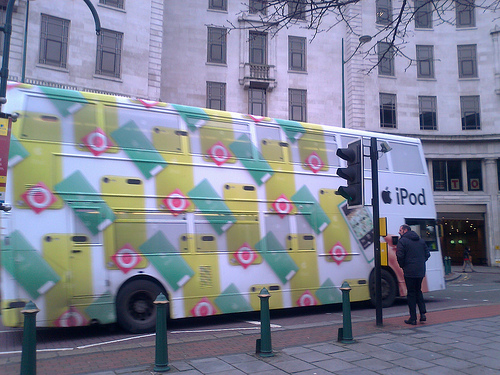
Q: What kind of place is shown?
A: It is a road.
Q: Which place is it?
A: It is a road.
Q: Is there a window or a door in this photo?
A: Yes, there is a window.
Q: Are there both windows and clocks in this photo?
A: No, there is a window but no clocks.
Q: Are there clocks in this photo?
A: No, there are no clocks.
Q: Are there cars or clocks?
A: No, there are no clocks or cars.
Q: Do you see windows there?
A: Yes, there is a window.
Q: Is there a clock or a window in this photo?
A: Yes, there is a window.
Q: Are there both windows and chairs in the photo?
A: No, there is a window but no chairs.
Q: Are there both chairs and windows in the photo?
A: No, there is a window but no chairs.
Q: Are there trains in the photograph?
A: No, there are no trains.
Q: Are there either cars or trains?
A: No, there are no trains or cars.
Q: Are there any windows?
A: Yes, there is a window.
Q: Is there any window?
A: Yes, there is a window.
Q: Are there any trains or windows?
A: Yes, there is a window.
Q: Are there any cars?
A: No, there are no cars.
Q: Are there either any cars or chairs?
A: No, there are no cars or chairs.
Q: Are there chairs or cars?
A: No, there are no cars or chairs.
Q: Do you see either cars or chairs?
A: No, there are no cars or chairs.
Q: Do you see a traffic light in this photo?
A: Yes, there is a traffic light.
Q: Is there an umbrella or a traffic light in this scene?
A: Yes, there is a traffic light.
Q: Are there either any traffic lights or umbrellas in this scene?
A: Yes, there is a traffic light.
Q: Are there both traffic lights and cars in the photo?
A: No, there is a traffic light but no cars.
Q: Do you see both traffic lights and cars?
A: No, there is a traffic light but no cars.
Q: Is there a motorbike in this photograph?
A: No, there are no motorcycles.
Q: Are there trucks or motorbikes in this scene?
A: No, there are no motorbikes or trucks.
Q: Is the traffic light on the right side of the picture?
A: Yes, the traffic light is on the right of the image.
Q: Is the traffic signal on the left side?
A: No, the traffic signal is on the right of the image.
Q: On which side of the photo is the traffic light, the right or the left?
A: The traffic light is on the right of the image.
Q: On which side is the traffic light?
A: The traffic light is on the right of the image.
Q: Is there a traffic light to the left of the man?
A: Yes, there is a traffic light to the left of the man.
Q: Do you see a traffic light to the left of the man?
A: Yes, there is a traffic light to the left of the man.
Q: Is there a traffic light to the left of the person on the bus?
A: Yes, there is a traffic light to the left of the man.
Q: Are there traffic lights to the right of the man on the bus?
A: No, the traffic light is to the left of the man.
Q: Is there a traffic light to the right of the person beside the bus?
A: No, the traffic light is to the left of the man.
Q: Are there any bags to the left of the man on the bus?
A: No, there is a traffic light to the left of the man.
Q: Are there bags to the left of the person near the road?
A: No, there is a traffic light to the left of the man.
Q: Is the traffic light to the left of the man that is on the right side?
A: Yes, the traffic light is to the left of the man.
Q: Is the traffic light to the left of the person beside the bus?
A: Yes, the traffic light is to the left of the man.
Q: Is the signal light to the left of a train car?
A: No, the signal light is to the left of the man.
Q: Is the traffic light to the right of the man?
A: No, the traffic light is to the left of the man.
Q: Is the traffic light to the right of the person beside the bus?
A: No, the traffic light is to the left of the man.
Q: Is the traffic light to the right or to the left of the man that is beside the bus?
A: The traffic light is to the left of the man.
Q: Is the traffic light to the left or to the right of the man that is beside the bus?
A: The traffic light is to the left of the man.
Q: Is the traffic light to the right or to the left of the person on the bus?
A: The traffic light is to the left of the man.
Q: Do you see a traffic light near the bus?
A: Yes, there is a traffic light near the bus.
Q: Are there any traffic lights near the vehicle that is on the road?
A: Yes, there is a traffic light near the bus.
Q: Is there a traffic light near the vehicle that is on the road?
A: Yes, there is a traffic light near the bus.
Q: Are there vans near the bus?
A: No, there is a traffic light near the bus.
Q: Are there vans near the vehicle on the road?
A: No, there is a traffic light near the bus.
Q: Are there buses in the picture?
A: Yes, there is a bus.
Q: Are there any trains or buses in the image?
A: Yes, there is a bus.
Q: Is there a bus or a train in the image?
A: Yes, there is a bus.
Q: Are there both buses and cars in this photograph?
A: No, there is a bus but no cars.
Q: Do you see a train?
A: No, there are no trains.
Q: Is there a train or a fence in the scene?
A: No, there are no trains or fences.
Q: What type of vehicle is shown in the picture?
A: The vehicle is a bus.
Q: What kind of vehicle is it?
A: The vehicle is a bus.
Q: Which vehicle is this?
A: This is a bus.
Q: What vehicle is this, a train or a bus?
A: This is a bus.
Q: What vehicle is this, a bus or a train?
A: This is a bus.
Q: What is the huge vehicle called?
A: The vehicle is a bus.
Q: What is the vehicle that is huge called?
A: The vehicle is a bus.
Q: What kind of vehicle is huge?
A: The vehicle is a bus.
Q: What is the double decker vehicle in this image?
A: The vehicle is a bus.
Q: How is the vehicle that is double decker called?
A: The vehicle is a bus.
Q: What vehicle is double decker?
A: The vehicle is a bus.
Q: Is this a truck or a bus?
A: This is a bus.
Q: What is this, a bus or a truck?
A: This is a bus.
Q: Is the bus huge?
A: Yes, the bus is huge.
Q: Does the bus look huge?
A: Yes, the bus is huge.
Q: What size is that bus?
A: The bus is huge.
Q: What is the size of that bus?
A: The bus is huge.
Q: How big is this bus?
A: The bus is huge.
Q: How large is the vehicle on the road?
A: The bus is huge.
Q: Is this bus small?
A: No, the bus is huge.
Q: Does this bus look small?
A: No, the bus is huge.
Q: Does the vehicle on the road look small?
A: No, the bus is huge.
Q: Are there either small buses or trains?
A: No, there is a bus but it is huge.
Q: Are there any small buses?
A: No, there is a bus but it is huge.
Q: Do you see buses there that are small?
A: No, there is a bus but it is huge.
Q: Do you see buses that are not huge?
A: No, there is a bus but it is huge.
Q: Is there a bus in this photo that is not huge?
A: No, there is a bus but it is huge.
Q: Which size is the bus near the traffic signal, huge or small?
A: The bus is huge.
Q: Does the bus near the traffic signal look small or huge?
A: The bus is huge.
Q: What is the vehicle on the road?
A: The vehicle is a bus.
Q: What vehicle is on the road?
A: The vehicle is a bus.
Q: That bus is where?
A: The bus is on the road.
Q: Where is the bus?
A: The bus is on the road.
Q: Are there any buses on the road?
A: Yes, there is a bus on the road.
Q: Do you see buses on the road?
A: Yes, there is a bus on the road.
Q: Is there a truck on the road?
A: No, there is a bus on the road.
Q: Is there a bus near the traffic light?
A: Yes, there is a bus near the traffic light.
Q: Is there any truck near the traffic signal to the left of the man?
A: No, there is a bus near the traffic signal.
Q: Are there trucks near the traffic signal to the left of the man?
A: No, there is a bus near the traffic signal.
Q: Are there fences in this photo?
A: No, there are no fences.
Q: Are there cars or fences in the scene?
A: No, there are no fences or cars.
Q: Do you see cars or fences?
A: No, there are no cars or fences.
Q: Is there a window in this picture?
A: Yes, there is a window.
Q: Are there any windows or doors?
A: Yes, there is a window.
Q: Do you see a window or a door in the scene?
A: Yes, there is a window.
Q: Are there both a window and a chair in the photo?
A: No, there is a window but no chairs.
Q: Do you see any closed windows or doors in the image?
A: Yes, there is a closed window.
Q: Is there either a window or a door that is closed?
A: Yes, the window is closed.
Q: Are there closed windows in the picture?
A: Yes, there is a closed window.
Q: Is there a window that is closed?
A: Yes, there is a window that is closed.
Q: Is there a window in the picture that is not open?
A: Yes, there is an closed window.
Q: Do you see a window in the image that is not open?
A: Yes, there is an closed window.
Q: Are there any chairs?
A: No, there are no chairs.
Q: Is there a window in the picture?
A: Yes, there is a window.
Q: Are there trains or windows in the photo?
A: Yes, there is a window.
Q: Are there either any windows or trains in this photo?
A: Yes, there is a window.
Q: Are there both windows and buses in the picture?
A: Yes, there are both a window and a bus.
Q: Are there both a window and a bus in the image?
A: Yes, there are both a window and a bus.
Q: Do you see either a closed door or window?
A: Yes, there is a closed window.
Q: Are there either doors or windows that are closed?
A: Yes, the window is closed.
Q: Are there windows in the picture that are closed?
A: Yes, there is a closed window.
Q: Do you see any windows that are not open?
A: Yes, there is an closed window.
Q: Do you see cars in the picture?
A: No, there are no cars.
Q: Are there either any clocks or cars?
A: No, there are no cars or clocks.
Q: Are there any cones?
A: No, there are no cones.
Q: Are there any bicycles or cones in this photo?
A: No, there are no cones or bicycles.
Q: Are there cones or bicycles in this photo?
A: No, there are no cones or bicycles.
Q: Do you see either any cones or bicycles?
A: No, there are no cones or bicycles.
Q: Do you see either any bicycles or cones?
A: No, there are no cones or bicycles.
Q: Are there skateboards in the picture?
A: No, there are no skateboards.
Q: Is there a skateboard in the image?
A: No, there are no skateboards.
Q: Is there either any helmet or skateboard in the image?
A: No, there are no skateboards or helmets.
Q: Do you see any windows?
A: Yes, there is a window.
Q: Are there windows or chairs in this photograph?
A: Yes, there is a window.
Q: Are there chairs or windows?
A: Yes, there is a window.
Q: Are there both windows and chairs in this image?
A: No, there is a window but no chairs.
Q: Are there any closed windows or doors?
A: Yes, there is a closed window.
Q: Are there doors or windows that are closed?
A: Yes, the window is closed.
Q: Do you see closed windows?
A: Yes, there is a closed window.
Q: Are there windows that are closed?
A: Yes, there is a window that is closed.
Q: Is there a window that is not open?
A: Yes, there is an closed window.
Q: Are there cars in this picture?
A: No, there are no cars.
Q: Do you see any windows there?
A: Yes, there is a window.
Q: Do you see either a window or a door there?
A: Yes, there is a window.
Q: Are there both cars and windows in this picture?
A: No, there is a window but no cars.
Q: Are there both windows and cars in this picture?
A: No, there is a window but no cars.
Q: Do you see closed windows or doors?
A: Yes, there is a closed window.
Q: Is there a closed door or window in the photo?
A: Yes, there is a closed window.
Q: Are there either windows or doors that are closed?
A: Yes, the window is closed.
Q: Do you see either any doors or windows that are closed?
A: Yes, the window is closed.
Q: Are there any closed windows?
A: Yes, there is a closed window.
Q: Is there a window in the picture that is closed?
A: Yes, there is a window that is closed.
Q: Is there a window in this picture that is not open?
A: Yes, there is an closed window.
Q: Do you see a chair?
A: No, there are no chairs.